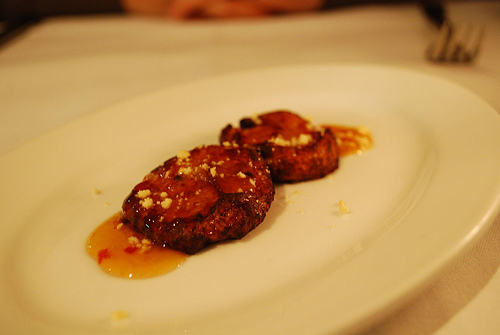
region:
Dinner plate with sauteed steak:
[0, 60, 499, 332]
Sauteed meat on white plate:
[87, 106, 374, 282]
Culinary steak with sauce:
[1, 60, 498, 333]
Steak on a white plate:
[6, 15, 494, 331]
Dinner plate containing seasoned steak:
[1, 1, 496, 332]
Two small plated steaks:
[119, 110, 342, 254]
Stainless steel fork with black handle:
[413, 0, 491, 68]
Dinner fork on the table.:
[411, 0, 491, 67]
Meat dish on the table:
[0, 5, 499, 333]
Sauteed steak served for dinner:
[1, 61, 498, 333]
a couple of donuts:
[118, 113, 348, 248]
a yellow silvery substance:
[83, 227, 179, 278]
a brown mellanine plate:
[279, 254, 441, 314]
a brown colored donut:
[154, 184, 249, 238]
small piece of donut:
[263, 125, 334, 174]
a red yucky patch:
[98, 250, 114, 265]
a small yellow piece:
[333, 200, 360, 217]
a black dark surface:
[4, 10, 46, 20]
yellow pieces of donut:
[138, 185, 170, 205]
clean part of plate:
[220, 279, 300, 307]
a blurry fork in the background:
[404, 11, 498, 78]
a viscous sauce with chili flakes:
[86, 212, 172, 294]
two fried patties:
[129, 142, 361, 262]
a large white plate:
[27, 70, 497, 313]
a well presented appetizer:
[44, 45, 444, 302]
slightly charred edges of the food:
[199, 204, 279, 251]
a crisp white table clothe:
[29, 8, 171, 85]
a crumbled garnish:
[139, 183, 182, 215]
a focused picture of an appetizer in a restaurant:
[3, 2, 485, 324]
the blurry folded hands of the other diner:
[122, 0, 351, 38]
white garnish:
[162, 199, 169, 206]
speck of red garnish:
[98, 248, 111, 259]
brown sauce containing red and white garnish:
[97, 230, 151, 271]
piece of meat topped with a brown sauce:
[123, 144, 273, 254]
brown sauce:
[95, 230, 157, 270]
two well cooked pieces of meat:
[119, 108, 362, 255]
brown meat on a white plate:
[120, 88, 345, 253]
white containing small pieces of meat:
[5, 62, 499, 333]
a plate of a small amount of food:
[1, 59, 498, 333]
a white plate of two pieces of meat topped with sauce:
[3, 55, 498, 323]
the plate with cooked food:
[93, 84, 400, 282]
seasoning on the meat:
[124, 138, 267, 221]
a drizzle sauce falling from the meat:
[71, 211, 218, 293]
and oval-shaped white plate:
[18, 60, 495, 295]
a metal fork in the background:
[422, 8, 478, 117]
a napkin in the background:
[112, 0, 348, 50]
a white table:
[18, 13, 496, 121]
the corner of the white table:
[3, 14, 145, 61]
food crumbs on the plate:
[318, 181, 381, 253]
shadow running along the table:
[11, 25, 366, 67]